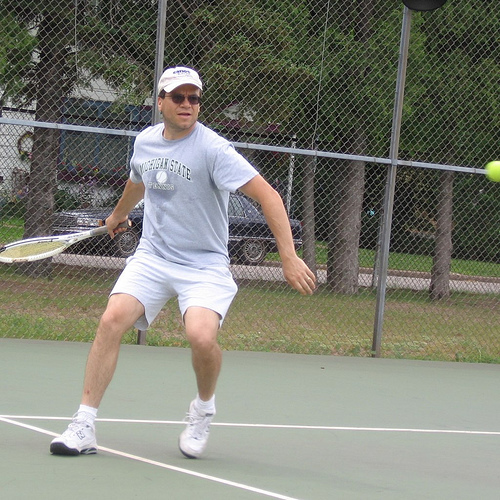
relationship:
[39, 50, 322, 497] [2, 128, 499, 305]
man playing tennis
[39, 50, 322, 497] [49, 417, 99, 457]
man wearing tennis shoe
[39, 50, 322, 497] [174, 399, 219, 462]
man wearing shoes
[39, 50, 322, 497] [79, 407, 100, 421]
man wearing socks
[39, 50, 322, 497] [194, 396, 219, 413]
man wearing socks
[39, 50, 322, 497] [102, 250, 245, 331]
man wearing shorts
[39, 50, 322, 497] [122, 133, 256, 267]
man wearing shirt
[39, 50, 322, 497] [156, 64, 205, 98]
man wearing hat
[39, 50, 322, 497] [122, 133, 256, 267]
man wearing a t-shirt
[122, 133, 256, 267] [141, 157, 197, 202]
t-shirt has a michigan state logo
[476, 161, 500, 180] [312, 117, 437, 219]
tennis ball flying through air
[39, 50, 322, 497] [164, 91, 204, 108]
man wearing eye-glasses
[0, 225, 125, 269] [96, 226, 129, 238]
tennis racket has a handle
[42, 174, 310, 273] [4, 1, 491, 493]
car parked behind tennis court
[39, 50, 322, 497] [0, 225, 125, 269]
man holding tennis racket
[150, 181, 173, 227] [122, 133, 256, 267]
sweat stains are on front of shirt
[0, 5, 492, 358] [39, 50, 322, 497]
fence behind man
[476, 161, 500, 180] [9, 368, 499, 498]
tennis ball flying above ground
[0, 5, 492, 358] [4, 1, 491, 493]
fence behind a tennis court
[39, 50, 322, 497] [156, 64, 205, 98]
man wearing a cap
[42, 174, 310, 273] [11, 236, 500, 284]
car parked on street side